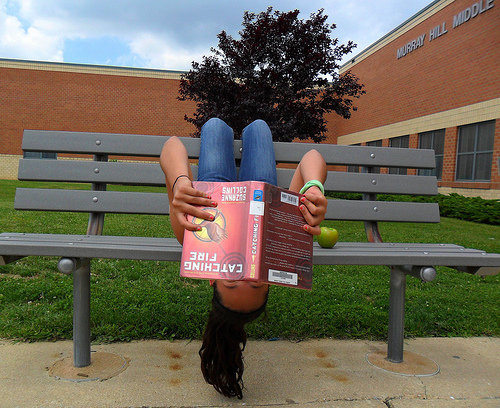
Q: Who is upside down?
A: Girl.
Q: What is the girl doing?
A: Reading.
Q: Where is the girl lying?
A: On a bench.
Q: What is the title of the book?
A: Catching Fire.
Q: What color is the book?
A: Red.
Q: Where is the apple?
A: On bench.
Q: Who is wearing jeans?
A: Girl.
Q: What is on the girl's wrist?
A: Bracelet.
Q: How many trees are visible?
A: 1.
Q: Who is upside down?
A: The girl on the bench.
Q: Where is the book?
A: In the girl's hands.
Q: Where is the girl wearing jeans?
A: Upside down on the bench.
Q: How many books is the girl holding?
A: One.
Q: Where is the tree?
A: Behind the bench.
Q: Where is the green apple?
A: Next to the girl.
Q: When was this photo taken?
A: During the daytime.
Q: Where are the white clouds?
A: In the sky.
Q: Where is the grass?
A: Behind the bench.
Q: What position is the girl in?
A: Upside down.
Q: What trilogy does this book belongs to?
A: The Hunger Games.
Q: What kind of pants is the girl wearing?
A: Blue jeans.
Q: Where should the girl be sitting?
A: Right side up.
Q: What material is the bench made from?
A: Wood.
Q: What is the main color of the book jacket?
A: Red.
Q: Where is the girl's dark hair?
A: Hanging down.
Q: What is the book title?
A: Catching Fire.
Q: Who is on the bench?
A: A girl reading a book.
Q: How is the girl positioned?
A: Upside down.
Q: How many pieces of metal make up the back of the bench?
A: Three.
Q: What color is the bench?
A: Gray.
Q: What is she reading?
A: A book.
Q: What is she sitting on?
A: Bench.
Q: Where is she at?
A: School.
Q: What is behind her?
A: A tree.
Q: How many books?
A: 1.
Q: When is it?
A: Daytime.